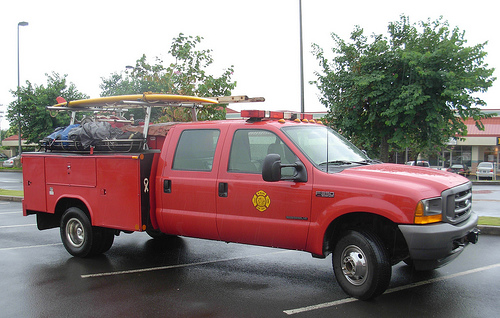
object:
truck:
[18, 94, 485, 302]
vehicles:
[447, 162, 468, 178]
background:
[381, 121, 497, 185]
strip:
[479, 211, 499, 228]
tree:
[316, 12, 493, 164]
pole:
[12, 19, 35, 159]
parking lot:
[0, 172, 498, 317]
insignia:
[250, 188, 273, 213]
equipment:
[40, 117, 149, 154]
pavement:
[1, 240, 498, 318]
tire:
[331, 227, 395, 301]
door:
[213, 124, 308, 254]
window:
[171, 124, 222, 172]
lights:
[239, 109, 321, 124]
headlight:
[411, 193, 449, 226]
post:
[296, 0, 312, 117]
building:
[434, 99, 498, 182]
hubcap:
[339, 244, 372, 287]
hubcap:
[62, 217, 85, 247]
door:
[156, 121, 218, 243]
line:
[77, 249, 255, 280]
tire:
[54, 203, 106, 258]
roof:
[455, 108, 499, 133]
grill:
[42, 92, 263, 115]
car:
[475, 161, 496, 181]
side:
[22, 125, 437, 297]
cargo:
[36, 91, 172, 155]